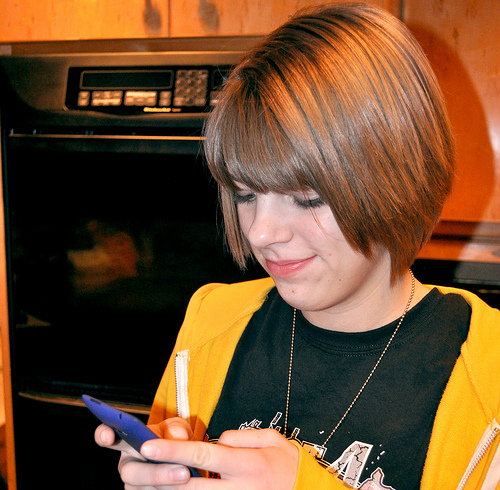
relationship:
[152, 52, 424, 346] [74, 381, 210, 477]
girl holding phone